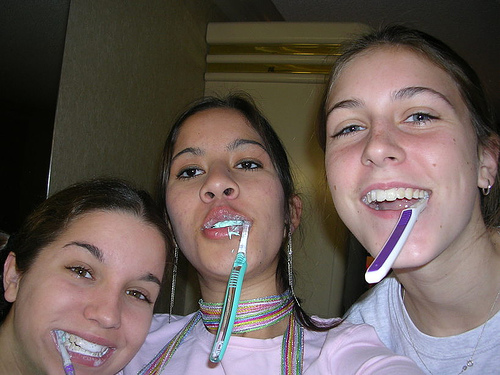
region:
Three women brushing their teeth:
[7, 17, 487, 372]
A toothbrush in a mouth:
[345, 175, 435, 285]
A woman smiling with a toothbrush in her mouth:
[5, 165, 175, 370]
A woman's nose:
[76, 281, 122, 331]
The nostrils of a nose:
[196, 180, 236, 201]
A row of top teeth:
[355, 182, 427, 202]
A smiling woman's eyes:
[316, 81, 456, 141]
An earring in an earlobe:
[475, 175, 495, 200]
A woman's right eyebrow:
[58, 236, 108, 270]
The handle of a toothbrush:
[204, 230, 252, 370]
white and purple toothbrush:
[363, 196, 430, 288]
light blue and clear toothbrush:
[206, 221, 249, 367]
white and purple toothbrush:
[52, 327, 72, 374]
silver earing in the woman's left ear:
[478, 177, 492, 199]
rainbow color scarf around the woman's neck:
[134, 292, 306, 374]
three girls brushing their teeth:
[2, 27, 497, 372]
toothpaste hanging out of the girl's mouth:
[204, 208, 252, 239]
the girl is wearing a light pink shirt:
[110, 312, 411, 373]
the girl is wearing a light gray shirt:
[331, 273, 499, 374]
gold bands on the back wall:
[203, 41, 349, 78]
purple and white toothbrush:
[363, 199, 431, 285]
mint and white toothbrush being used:
[210, 220, 258, 361]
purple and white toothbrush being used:
[57, 337, 79, 374]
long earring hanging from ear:
[283, 223, 303, 310]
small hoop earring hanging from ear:
[485, 179, 491, 196]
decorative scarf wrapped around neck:
[138, 288, 304, 373]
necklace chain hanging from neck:
[396, 294, 497, 373]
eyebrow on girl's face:
[62, 241, 104, 262]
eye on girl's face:
[402, 110, 439, 125]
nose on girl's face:
[198, 165, 240, 202]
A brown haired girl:
[5, 175, 177, 373]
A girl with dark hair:
[114, 90, 426, 373]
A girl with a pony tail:
[312, 28, 499, 373]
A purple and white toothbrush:
[53, 328, 75, 373]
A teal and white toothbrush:
[209, 222, 251, 368]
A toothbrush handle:
[365, 199, 426, 284]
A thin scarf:
[135, 288, 307, 373]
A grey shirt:
[343, 276, 499, 373]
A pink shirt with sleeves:
[114, 308, 427, 373]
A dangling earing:
[284, 225, 301, 310]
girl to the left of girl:
[1, 178, 173, 373]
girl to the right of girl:
[118, 95, 339, 374]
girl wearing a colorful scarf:
[135, 288, 304, 373]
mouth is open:
[52, 325, 114, 367]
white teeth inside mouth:
[61, 333, 108, 358]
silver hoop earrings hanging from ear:
[482, 177, 492, 193]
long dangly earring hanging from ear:
[285, 225, 300, 310]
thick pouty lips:
[201, 206, 253, 238]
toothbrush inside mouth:
[363, 194, 434, 284]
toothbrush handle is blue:
[207, 253, 245, 368]